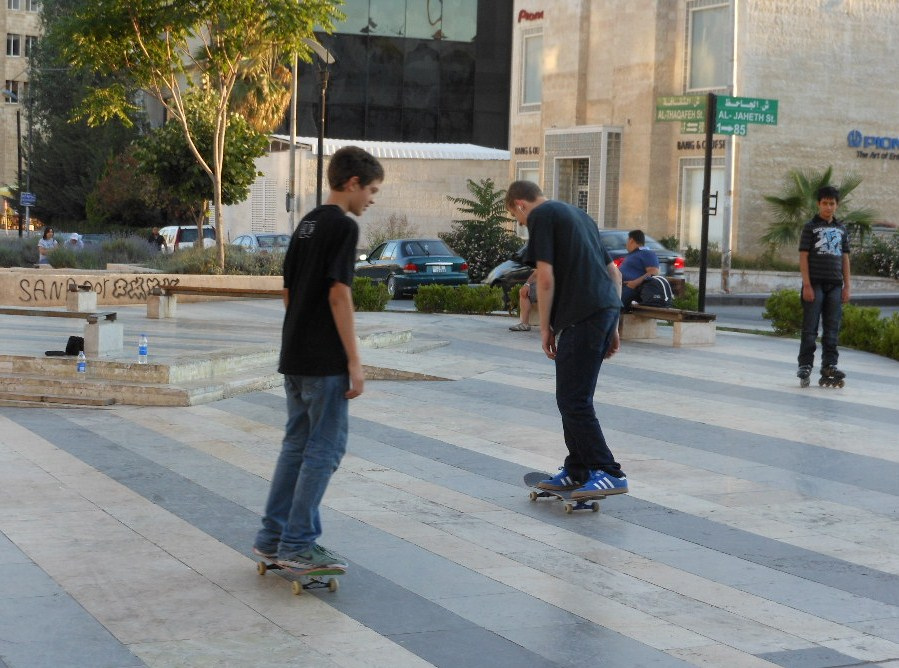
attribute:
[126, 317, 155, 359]
water bottle — plastic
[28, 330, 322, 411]
steps — concrete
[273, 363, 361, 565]
jeans — blue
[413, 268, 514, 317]
bushes — green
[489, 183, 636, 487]
boy — young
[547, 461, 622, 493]
tennis shoes — blue, white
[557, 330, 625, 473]
jeans — black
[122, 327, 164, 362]
water bottle — plastic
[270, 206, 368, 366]
shirt — black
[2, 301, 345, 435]
steps — concrete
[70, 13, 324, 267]
tree — thin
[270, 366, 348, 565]
jeans — blue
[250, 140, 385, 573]
kid — skateboarding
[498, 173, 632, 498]
kid — skateboarding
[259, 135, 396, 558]
boy — young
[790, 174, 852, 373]
boy — young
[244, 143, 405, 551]
boy — young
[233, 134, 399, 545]
boy — young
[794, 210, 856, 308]
shirt — black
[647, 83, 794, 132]
street signs — green, white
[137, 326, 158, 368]
water bottle — plastic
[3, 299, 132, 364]
bench — concrete, empty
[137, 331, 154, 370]
water bottle — plastic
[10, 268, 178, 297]
graffiti — Black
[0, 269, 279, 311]
wall — sandstone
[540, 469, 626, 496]
shoes — blue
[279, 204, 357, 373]
shirt — black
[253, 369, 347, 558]
jeans — blue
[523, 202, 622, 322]
shirt — black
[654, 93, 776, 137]
street signs — Green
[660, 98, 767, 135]
lettering — white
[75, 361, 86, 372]
packaging — blue 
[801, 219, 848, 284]
top — green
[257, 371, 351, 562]
jeans — blue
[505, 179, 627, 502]
man — young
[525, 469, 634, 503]
shoes — blue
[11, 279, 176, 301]
grafitti — small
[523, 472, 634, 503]
shoes — blue, white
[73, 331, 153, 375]
water bottles — Clear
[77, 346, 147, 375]
labels — blue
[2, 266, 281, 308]
wall — short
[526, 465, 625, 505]
shoes — blue , white, adidas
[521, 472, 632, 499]
shoes — adidas, blue , white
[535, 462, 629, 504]
shoes — blue, white, Adidas brand